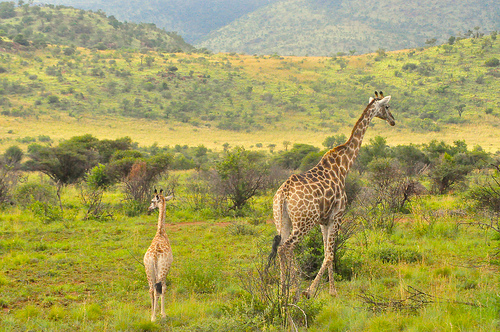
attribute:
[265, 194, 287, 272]
tail — black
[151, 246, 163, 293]
tail — black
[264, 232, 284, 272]
black hair — long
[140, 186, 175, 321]
giraffe — small, brown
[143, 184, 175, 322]
smaller giraffe — small, lighter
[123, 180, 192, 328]
giraffe — small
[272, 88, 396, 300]
giraffes — wild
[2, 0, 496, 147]
hills — rolling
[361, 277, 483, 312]
branch — brown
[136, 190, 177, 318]
giraffe — brown, small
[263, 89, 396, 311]
adult giraffe — tan, brown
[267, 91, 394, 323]
giraffe — brown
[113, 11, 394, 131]
mountains — filling the background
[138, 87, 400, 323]
two giraffes — walking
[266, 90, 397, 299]
giraffe — walking, adult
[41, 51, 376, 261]
trees — small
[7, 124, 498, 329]
land — flat, full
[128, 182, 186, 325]
giraffe — juvenile, standing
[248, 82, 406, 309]
giraffe — large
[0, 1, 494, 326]
grass — green